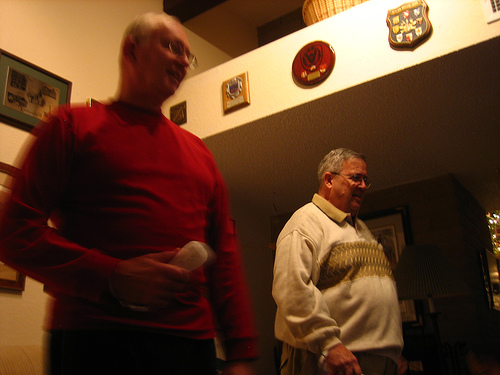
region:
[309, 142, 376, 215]
the head of a man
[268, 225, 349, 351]
the arm of a man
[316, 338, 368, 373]
the hand of a man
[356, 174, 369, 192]
the nose of a man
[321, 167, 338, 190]
the ear of a man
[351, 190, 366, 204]
the mouth of a man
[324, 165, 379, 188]
a pair of glasses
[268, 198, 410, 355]
a white and green sweater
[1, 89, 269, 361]
a red shirt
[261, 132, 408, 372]
a man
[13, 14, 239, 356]
old man in red sweater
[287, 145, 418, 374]
old man in white sweater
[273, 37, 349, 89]
red monument on wall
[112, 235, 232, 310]
hand carrying object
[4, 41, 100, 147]
picture frame on the wall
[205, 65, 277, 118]
yellow wall piece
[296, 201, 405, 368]
sweater with stripe across the middle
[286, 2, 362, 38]
wooden woven basket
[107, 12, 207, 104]
old man wearing glasses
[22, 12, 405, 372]
two men in a room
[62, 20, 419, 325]
Two men playing wii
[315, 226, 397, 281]
Stripe on sweater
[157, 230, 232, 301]
Holding wii remote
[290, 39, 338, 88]
Red plate on wall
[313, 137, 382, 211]
Short gray hair on head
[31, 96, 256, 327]
Wearing red sweater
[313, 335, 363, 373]
Red hand is wrinkled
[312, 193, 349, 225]
Yellow collar of undershirt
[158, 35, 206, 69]
Glasses of man on face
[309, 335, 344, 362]
Clasp on right wrist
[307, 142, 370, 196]
gray and white hair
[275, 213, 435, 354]
tan and brown sweater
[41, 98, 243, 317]
red sweater on man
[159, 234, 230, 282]
white wii remote in hand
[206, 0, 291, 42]
small nook above ceiling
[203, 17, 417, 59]
a row of plaques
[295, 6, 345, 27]
a wicker basket on the shelf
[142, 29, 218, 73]
glasses with silver frames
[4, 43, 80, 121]
green mat with brown frame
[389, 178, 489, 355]
someone standing in the dark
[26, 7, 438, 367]
Two older men playing a wii game.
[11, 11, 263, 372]
Man on left wearing red shirt.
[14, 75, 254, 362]
Man on left wearing long sleeve shirt.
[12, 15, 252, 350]
Man on left holding wii control.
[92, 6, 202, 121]
Man on left has on glasses.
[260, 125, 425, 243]
Man on right has on glasses.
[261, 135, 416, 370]
Man on right has on white and brown shirt.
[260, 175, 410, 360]
Man on right has on long sleeve shirt.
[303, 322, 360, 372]
Man on right has wii control on right wrist.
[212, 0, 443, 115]
Three decorative plaques on wall.